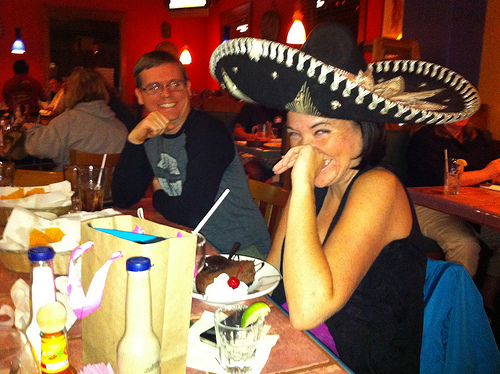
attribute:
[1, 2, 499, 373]
restaurant — crowded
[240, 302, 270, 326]
lime — fresh, green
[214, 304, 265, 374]
glass — shot glass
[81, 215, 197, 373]
bag — gift bag, brown, paper, yellow, browny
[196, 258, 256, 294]
cake — chocolate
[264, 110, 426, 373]
woman — laughing, smiling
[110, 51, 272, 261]
man — smiling, blond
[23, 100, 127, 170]
hoodie — gray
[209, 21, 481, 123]
sombrero — black, gold, large, blacl, silver, big, mexican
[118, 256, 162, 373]
pepper shaker — beer bottle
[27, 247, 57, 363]
salt shaker — beer bottle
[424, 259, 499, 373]
windbreaker — blue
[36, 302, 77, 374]
bottle — hot sauce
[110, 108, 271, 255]
shirt — black, gray, long-sleeve, long sleeve, tee shirt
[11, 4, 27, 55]
lamp — hanging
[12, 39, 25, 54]
shade — blue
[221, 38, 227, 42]
light — blue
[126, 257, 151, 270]
lid — blue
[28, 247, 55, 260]
lid — blue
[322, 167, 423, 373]
dress — sleeveless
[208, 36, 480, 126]
trim — silver